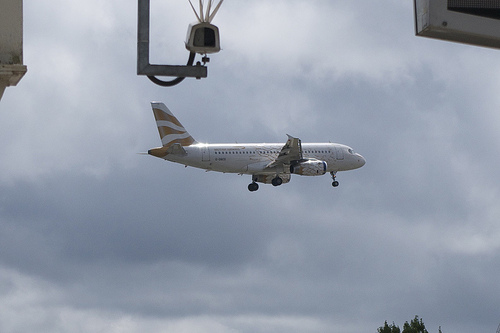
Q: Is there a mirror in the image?
A: No, there are no mirrors.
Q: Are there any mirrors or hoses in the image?
A: No, there are no mirrors or hoses.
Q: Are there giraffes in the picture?
A: No, there are no giraffes.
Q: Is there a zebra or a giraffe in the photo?
A: No, there are no giraffes or zebras.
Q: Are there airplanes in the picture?
A: Yes, there is an airplane.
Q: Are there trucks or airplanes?
A: Yes, there is an airplane.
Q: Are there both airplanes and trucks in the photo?
A: No, there is an airplane but no trucks.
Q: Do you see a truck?
A: No, there are no trucks.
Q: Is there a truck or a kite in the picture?
A: No, there are no trucks or kites.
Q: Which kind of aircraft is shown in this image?
A: The aircraft is an airplane.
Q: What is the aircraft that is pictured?
A: The aircraft is an airplane.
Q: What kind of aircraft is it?
A: The aircraft is an airplane.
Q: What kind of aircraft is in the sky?
A: The aircraft is an airplane.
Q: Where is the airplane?
A: The airplane is in the sky.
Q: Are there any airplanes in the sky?
A: Yes, there is an airplane in the sky.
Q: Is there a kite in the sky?
A: No, there is an airplane in the sky.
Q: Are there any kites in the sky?
A: No, there is an airplane in the sky.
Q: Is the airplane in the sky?
A: Yes, the airplane is in the sky.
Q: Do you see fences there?
A: No, there are no fences.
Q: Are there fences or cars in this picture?
A: No, there are no fences or cars.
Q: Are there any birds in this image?
A: No, there are no birds.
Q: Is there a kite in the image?
A: No, there are no kites.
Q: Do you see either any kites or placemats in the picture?
A: No, there are no kites or placemats.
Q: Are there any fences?
A: No, there are no fences.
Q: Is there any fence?
A: No, there are no fences.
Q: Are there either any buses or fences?
A: No, there are no fences or buses.